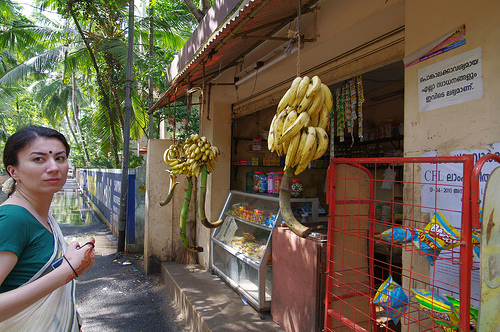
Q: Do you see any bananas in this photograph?
A: Yes, there are bananas.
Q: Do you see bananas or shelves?
A: Yes, there are bananas.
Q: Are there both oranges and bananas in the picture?
A: No, there are bananas but no oranges.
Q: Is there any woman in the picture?
A: Yes, there is a woman.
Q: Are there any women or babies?
A: Yes, there is a woman.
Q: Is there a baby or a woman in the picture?
A: Yes, there is a woman.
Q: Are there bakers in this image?
A: No, there are no bakers.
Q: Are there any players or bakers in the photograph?
A: No, there are no bakers or players.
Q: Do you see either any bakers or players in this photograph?
A: No, there are no bakers or players.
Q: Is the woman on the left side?
A: Yes, the woman is on the left of the image.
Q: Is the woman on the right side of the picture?
A: No, the woman is on the left of the image.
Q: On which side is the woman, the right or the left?
A: The woman is on the left of the image.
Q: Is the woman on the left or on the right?
A: The woman is on the left of the image.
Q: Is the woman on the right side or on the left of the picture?
A: The woman is on the left of the image.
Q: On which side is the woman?
A: The woman is on the left of the image.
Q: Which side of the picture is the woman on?
A: The woman is on the left of the image.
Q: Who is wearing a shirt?
A: The woman is wearing a shirt.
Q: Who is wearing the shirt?
A: The woman is wearing a shirt.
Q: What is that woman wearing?
A: The woman is wearing a shirt.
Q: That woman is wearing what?
A: The woman is wearing a shirt.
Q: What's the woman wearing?
A: The woman is wearing a shirt.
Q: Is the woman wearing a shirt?
A: Yes, the woman is wearing a shirt.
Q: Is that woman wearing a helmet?
A: No, the woman is wearing a shirt.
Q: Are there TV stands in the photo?
A: No, there are no TV stands.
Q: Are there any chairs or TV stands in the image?
A: No, there are no TV stands or chairs.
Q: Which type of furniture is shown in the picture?
A: The furniture is a shelf.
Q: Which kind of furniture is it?
A: The piece of furniture is a shelf.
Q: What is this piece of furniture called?
A: That is a shelf.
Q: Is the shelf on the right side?
A: Yes, the shelf is on the right of the image.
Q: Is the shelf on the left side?
A: No, the shelf is on the right of the image.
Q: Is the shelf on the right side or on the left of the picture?
A: The shelf is on the right of the image.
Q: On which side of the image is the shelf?
A: The shelf is on the right of the image.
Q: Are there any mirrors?
A: No, there are no mirrors.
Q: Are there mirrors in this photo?
A: No, there are no mirrors.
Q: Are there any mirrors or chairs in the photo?
A: No, there are no mirrors or chairs.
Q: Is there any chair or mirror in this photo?
A: No, there are no mirrors or chairs.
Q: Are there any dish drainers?
A: No, there are no dish drainers.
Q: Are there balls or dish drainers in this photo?
A: No, there are no dish drainers or balls.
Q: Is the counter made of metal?
A: Yes, the counter is made of metal.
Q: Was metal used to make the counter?
A: Yes, the counter is made of metal.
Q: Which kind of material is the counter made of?
A: The counter is made of metal.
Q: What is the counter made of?
A: The counter is made of metal.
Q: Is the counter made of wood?
A: No, the counter is made of metal.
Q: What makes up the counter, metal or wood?
A: The counter is made of metal.